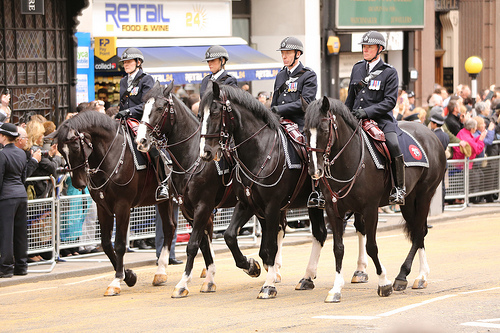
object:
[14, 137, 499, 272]
fence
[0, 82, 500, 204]
crowd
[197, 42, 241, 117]
person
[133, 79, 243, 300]
horse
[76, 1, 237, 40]
sign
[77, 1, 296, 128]
business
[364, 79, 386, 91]
blazer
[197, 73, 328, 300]
horse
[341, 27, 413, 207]
rider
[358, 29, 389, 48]
helmet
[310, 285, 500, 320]
lines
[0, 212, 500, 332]
floor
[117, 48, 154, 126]
police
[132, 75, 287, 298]
horse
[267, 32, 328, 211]
person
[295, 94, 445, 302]
horse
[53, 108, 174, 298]
horse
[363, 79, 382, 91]
patch